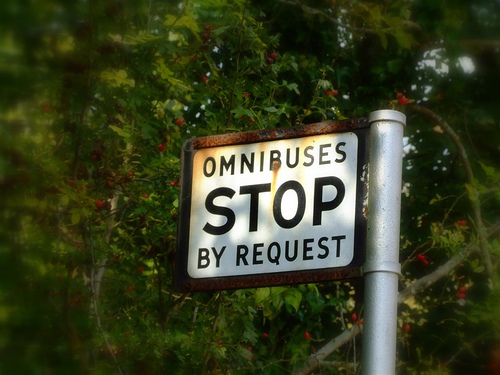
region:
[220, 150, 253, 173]
The letters MN on the sign.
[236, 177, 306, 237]
The letters TO on the sign.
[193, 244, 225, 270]
The letters BY on the sign.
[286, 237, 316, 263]
The letters UE in the word REQUEST.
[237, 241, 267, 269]
The letters RE in the word REQUEST.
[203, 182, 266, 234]
The letters ST in the word STOP.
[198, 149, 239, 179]
The letters OM in the word OMNIBUSES.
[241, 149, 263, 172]
The letters NI in the word OMNIBUSES.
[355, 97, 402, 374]
The gray pole the sign is mounted to.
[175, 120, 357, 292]
The rusted frame around the sign.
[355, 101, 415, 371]
The gray pole the sign is mounted on.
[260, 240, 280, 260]
The letter Q on the sign.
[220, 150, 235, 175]
The letter M on the sign.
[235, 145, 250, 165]
The N on the sign.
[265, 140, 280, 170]
The letter B in the word Omnibuses on the sign.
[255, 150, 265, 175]
The letter I on the sign.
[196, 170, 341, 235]
The word Stop on the sign.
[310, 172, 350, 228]
The letter P on the sign.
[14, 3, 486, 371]
The green leaves on the trees.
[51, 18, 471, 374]
The red berries on the trees.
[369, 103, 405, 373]
The pole the sign is mounted to.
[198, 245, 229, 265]
The word By on the sign.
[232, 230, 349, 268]
The word Request on the sign.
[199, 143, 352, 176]
The word Omnibuses on the sign.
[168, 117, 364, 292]
The border of the sign.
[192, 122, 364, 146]
The rust spots on the border frame at the top of the sign.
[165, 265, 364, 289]
The rust spots on the border frame at the bottom of the sign.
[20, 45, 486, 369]
The red berries on the trees behind the sign.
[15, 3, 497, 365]
The green leaves of the trees behind the sign.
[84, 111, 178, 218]
Red berries on tree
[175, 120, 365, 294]
Metal framed information sign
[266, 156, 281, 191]
Rust stain on sign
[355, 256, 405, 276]
Metal sign bracket on pole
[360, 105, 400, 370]
Grey metal sign pole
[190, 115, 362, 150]
Metal frame covered with rust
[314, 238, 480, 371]
Wooden branch of tree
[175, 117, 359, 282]
Bus stop information sign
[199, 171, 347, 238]
Black lettered STOP on white sign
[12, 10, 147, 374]
Blurry leaf covered trees in background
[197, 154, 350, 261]
Sign post for bus stop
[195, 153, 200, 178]
Rust smear on white surface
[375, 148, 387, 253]
Metallic pole standing upright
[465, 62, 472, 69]
Sky visible through the plant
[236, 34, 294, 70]
Shadow cast on the plant